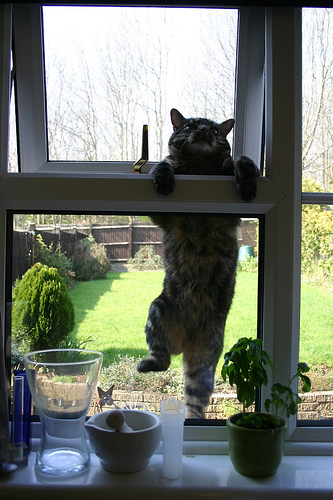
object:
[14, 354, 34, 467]
vase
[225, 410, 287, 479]
pot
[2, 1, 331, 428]
window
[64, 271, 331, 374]
grass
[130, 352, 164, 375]
right foot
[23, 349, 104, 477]
hourglass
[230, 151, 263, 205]
legs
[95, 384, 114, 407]
no dog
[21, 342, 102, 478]
vase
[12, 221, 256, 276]
fence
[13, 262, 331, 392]
back yard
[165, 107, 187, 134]
ear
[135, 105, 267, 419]
cat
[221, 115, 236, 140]
ear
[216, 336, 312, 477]
potted plant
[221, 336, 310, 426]
plant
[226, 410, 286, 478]
container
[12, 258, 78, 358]
bush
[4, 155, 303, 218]
plastic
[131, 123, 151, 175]
window latch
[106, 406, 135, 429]
pestle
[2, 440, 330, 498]
windowsil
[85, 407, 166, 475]
mortar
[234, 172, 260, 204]
paws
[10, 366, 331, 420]
brick wall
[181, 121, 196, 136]
eye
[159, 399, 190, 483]
container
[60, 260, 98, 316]
shade